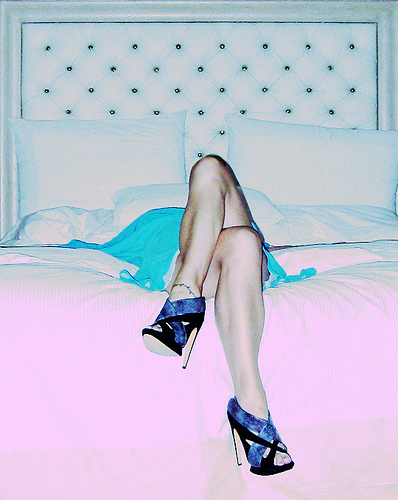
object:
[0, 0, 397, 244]
headboard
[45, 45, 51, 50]
nail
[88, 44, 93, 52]
nail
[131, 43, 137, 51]
nail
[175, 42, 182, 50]
nail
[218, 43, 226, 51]
nail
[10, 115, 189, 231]
pillow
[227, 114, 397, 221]
pillow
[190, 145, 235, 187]
knee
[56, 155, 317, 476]
woman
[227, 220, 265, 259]
knee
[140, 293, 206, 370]
shoe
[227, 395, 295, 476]
shoe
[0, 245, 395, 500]
cover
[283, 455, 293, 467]
toes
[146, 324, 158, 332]
toes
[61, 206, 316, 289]
dress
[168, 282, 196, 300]
tattoo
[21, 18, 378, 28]
lines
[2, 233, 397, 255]
lines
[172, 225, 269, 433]
legs